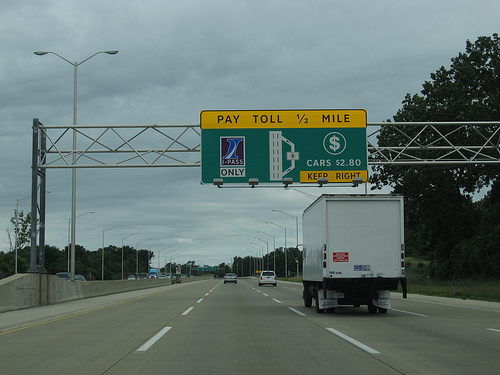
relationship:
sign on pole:
[204, 111, 359, 183] [44, 116, 493, 159]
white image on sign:
[267, 129, 298, 183] [201, 109, 368, 182]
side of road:
[3, 270, 215, 306] [36, 210, 373, 374]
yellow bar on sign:
[198, 107, 369, 130] [198, 108, 368, 188]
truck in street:
[301, 194, 407, 314] [34, 263, 483, 373]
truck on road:
[258, 157, 452, 357] [42, 241, 492, 364]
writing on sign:
[252, 110, 284, 124] [193, 111, 365, 179]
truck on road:
[301, 194, 407, 314] [5, 272, 495, 370]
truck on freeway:
[301, 194, 407, 314] [6, 268, 498, 373]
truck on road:
[292, 189, 412, 319] [5, 272, 495, 370]